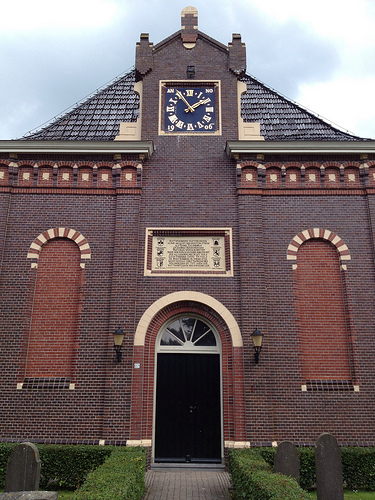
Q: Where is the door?
A: On building.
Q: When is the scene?
A: During daytime.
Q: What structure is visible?
A: Building.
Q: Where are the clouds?
A: Sky.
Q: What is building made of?
A: Bricks.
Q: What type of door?
A: Double.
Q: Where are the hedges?
A: Front yard.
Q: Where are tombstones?
A: Front yard.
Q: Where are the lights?
A: On wall.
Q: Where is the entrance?
A: On building.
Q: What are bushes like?
A: Shaved.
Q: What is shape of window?
A: Rounded.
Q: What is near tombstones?
A: Shrubs.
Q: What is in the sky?
A: Clouds.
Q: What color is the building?
A: Red.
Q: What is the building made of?
A: Brick.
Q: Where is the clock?
A: The top of the building.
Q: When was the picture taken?
A: Daytime.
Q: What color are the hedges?
A: Green.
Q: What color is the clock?
A: Black and gold.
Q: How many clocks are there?
A: One.